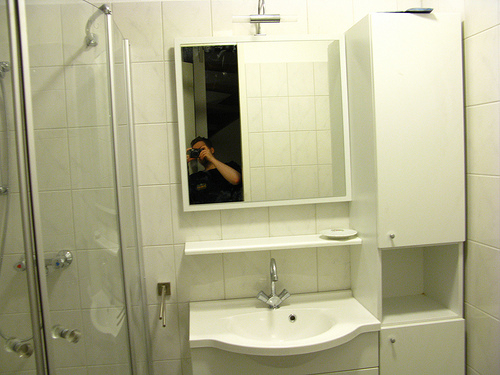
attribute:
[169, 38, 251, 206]
mirror — tall, thin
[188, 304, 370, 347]
sink — porcelain, white, bright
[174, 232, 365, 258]
shelf — white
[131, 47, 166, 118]
tile wall — white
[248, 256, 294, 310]
faucet — silver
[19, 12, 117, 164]
doors — glass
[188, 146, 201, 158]
camera — black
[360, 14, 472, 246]
cupboard — long, white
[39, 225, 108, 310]
shower door — clear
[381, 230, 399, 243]
cabinet handle — silver, tiny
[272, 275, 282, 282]
spout — tall, white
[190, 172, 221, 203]
shirt — black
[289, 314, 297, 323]
hole — silver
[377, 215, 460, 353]
cabinets — white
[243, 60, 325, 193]
wall — tiled